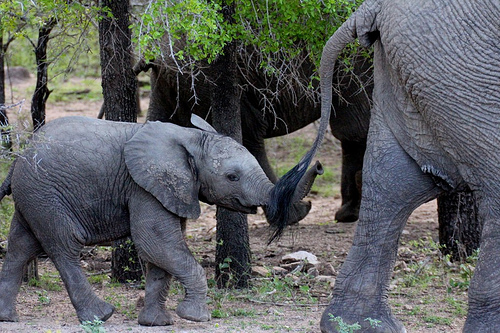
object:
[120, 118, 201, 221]
ear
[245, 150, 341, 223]
elephant trunk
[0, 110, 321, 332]
elephant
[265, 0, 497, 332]
elephant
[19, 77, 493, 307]
ground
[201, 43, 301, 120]
branches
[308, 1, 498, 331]
skin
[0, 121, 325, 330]
skin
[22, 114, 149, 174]
back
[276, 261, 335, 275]
rocks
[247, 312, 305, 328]
sand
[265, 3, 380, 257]
tail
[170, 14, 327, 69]
leaves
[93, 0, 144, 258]
trees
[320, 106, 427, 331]
leg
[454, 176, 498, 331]
leg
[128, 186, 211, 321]
leg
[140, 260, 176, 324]
leg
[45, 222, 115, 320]
leg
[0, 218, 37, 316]
leg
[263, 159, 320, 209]
trunk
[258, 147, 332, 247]
hair